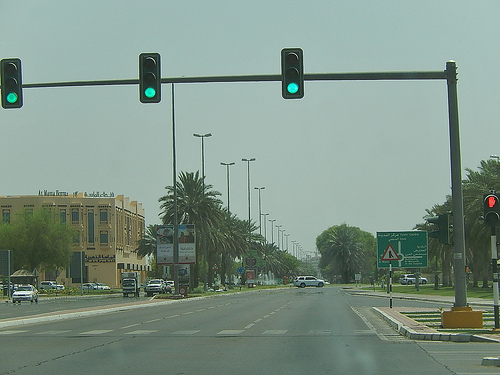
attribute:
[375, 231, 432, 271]
sign — green, white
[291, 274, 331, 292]
suv — white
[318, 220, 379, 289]
trees — palm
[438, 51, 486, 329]
post — white, black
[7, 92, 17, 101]
light — green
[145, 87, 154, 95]
light — green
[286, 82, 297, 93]
light — green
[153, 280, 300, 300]
divider — center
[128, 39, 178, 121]
light — green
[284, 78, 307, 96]
light — green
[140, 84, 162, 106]
light — green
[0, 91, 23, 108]
light — green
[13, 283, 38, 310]
car — parked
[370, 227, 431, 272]
sign post — blue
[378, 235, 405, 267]
sign — red, white, black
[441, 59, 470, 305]
post — black, white, striped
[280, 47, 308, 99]
traffic light — green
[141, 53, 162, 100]
traffic light — green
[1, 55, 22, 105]
traffic light — green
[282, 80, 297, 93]
green — light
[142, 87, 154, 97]
green — light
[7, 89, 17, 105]
green — light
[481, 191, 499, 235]
traffic light — red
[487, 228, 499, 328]
pole — black, white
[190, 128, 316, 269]
lights — street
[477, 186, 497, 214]
sign — DO NOT CROSS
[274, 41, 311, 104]
light — green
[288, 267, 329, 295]
car — white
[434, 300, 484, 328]
base — yellow